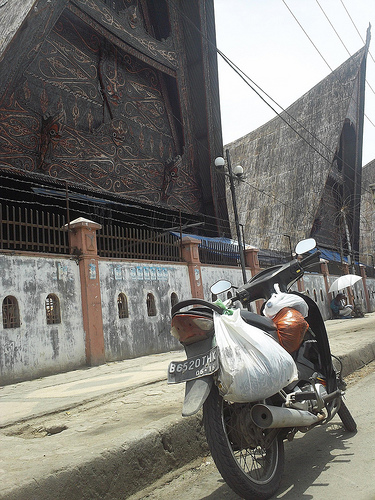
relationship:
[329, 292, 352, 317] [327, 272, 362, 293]
person under umbrella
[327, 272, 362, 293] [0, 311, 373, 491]
umbrella on sidewalk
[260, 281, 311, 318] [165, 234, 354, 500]
plastic bag on bike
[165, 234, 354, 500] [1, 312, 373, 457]
bike by sidewalk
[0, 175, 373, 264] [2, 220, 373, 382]
barbed wires on wall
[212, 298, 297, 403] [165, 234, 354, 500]
bag on bike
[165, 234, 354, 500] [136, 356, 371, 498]
bike on road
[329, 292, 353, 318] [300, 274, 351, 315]
person on wall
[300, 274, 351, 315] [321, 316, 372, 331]
wall on ground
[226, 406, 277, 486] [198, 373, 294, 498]
spokes on wheel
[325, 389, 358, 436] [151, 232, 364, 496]
front wheel on bike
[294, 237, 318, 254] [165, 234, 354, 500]
mirror on bike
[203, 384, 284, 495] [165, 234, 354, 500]
back wheel on bike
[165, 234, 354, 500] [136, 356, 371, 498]
bike parked on side of road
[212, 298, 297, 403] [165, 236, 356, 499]
bag hanging off bike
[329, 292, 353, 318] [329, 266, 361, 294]
person sitting under an umbrella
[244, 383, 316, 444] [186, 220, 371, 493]
pipe on bike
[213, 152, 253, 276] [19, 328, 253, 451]
lamp near sidewalk.